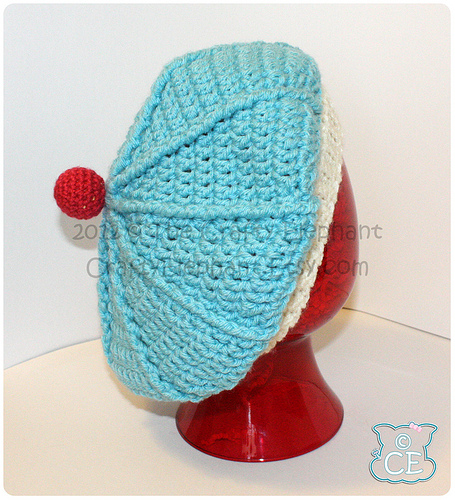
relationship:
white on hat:
[257, 80, 348, 370] [46, 37, 356, 413]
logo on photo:
[340, 406, 450, 478] [4, 7, 441, 496]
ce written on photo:
[382, 449, 424, 476] [4, 7, 441, 496]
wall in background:
[56, 55, 124, 122] [2, 3, 439, 401]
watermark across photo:
[62, 208, 409, 296] [4, 7, 441, 496]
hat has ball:
[46, 37, 356, 413] [51, 165, 108, 223]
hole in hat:
[210, 257, 225, 271] [23, 42, 376, 381]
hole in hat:
[163, 228, 181, 245] [23, 42, 376, 381]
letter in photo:
[379, 447, 405, 478] [4, 7, 441, 496]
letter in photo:
[402, 449, 425, 478] [4, 7, 441, 496]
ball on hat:
[56, 165, 106, 218] [46, 37, 356, 413]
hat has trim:
[46, 37, 356, 413] [314, 75, 347, 302]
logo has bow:
[364, 419, 440, 488] [407, 421, 420, 432]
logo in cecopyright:
[364, 419, 440, 488] [365, 416, 444, 494]